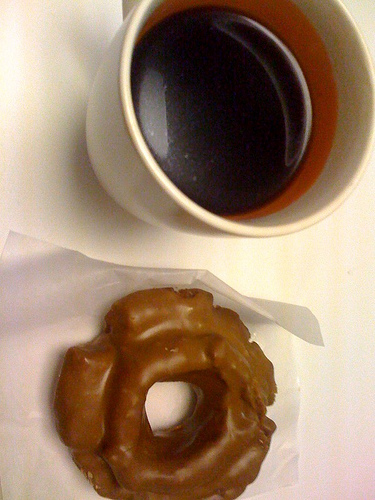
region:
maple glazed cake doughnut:
[50, 288, 295, 491]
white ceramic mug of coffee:
[82, 2, 372, 252]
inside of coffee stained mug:
[121, 5, 365, 224]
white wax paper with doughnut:
[7, 238, 322, 484]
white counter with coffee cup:
[10, 7, 374, 491]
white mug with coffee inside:
[54, 0, 374, 249]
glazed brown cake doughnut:
[50, 283, 297, 487]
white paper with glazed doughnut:
[1, 222, 337, 495]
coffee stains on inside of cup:
[122, 0, 373, 233]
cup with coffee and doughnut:
[39, 0, 373, 496]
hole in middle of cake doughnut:
[139, 358, 219, 446]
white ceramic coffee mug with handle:
[74, 1, 374, 264]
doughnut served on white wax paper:
[0, 221, 335, 495]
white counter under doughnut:
[5, 4, 374, 499]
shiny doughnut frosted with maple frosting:
[48, 283, 286, 496]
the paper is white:
[4, 311, 70, 497]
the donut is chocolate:
[67, 326, 271, 484]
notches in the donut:
[70, 311, 257, 369]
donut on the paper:
[51, 278, 264, 498]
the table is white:
[291, 335, 365, 488]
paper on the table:
[272, 340, 359, 494]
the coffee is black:
[146, 17, 330, 199]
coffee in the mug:
[85, 43, 338, 250]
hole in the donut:
[106, 354, 249, 468]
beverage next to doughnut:
[17, 5, 362, 492]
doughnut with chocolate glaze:
[48, 283, 274, 495]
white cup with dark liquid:
[81, 0, 367, 234]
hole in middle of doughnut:
[56, 285, 274, 495]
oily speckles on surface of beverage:
[130, 2, 206, 190]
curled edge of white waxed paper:
[3, 217, 322, 491]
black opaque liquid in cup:
[126, 7, 310, 212]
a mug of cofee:
[70, 31, 371, 267]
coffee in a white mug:
[88, 66, 340, 281]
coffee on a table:
[80, 30, 367, 277]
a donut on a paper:
[75, 277, 349, 497]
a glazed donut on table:
[80, 283, 316, 495]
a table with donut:
[22, 275, 339, 493]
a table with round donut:
[84, 279, 335, 497]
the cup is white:
[85, 0, 372, 237]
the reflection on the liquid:
[130, 4, 314, 216]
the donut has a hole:
[51, 287, 278, 498]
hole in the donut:
[83, 324, 266, 469]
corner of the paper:
[271, 269, 346, 371]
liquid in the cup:
[108, 15, 347, 189]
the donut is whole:
[54, 286, 276, 498]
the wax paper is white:
[0, 230, 323, 499]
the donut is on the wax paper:
[0, 230, 324, 497]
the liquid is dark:
[131, 6, 314, 217]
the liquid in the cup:
[86, 0, 374, 238]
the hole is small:
[144, 380, 197, 433]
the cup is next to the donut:
[1, 0, 373, 498]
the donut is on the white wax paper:
[1, 230, 324, 498]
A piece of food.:
[17, 283, 274, 498]